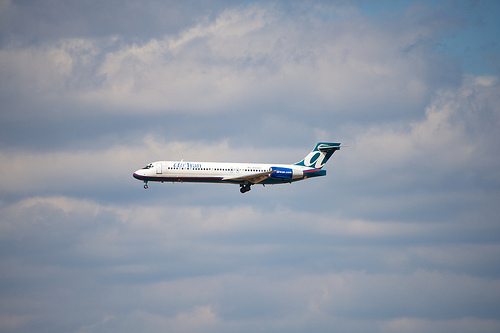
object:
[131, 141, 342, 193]
bird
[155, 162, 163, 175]
door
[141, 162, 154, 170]
windows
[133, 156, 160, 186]
cockpit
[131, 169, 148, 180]
nose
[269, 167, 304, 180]
jet engine